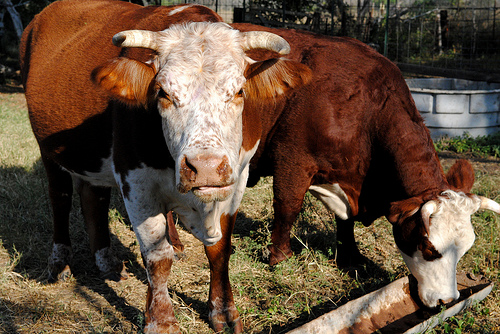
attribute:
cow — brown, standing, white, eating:
[17, 2, 317, 332]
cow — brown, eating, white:
[251, 24, 500, 311]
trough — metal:
[278, 269, 489, 333]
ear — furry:
[242, 55, 317, 105]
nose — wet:
[177, 153, 236, 188]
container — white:
[403, 70, 499, 145]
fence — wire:
[261, 6, 498, 58]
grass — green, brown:
[1, 90, 348, 334]